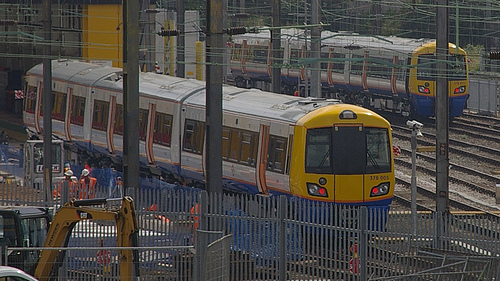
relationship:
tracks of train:
[300, 108, 497, 280] [16, 52, 402, 252]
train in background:
[225, 22, 477, 123] [135, 7, 499, 94]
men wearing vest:
[79, 165, 104, 206] [79, 176, 98, 196]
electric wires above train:
[3, 4, 498, 77] [16, 52, 402, 252]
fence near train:
[7, 175, 498, 277] [16, 52, 402, 252]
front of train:
[291, 104, 399, 257] [16, 52, 402, 252]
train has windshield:
[16, 52, 402, 252] [305, 121, 395, 175]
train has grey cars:
[16, 52, 402, 252] [18, 45, 298, 231]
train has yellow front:
[16, 52, 402, 252] [291, 104, 399, 257]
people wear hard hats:
[44, 158, 208, 238] [64, 168, 91, 176]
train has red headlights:
[16, 52, 402, 252] [317, 183, 381, 198]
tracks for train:
[300, 108, 497, 280] [16, 52, 402, 252]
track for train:
[378, 106, 496, 280] [16, 52, 402, 252]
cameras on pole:
[401, 112, 427, 241] [409, 129, 423, 248]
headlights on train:
[307, 182, 394, 201] [16, 52, 402, 252]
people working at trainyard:
[44, 158, 208, 238] [4, 149, 243, 279]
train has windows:
[16, 52, 402, 252] [24, 79, 290, 173]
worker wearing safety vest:
[145, 201, 171, 223] [144, 213, 168, 225]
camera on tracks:
[401, 112, 427, 241] [300, 108, 497, 280]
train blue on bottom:
[16, 52, 402, 252] [242, 190, 393, 229]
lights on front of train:
[307, 182, 394, 201] [16, 52, 402, 252]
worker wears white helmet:
[58, 167, 80, 200] [62, 168, 75, 177]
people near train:
[44, 158, 208, 238] [150, 73, 390, 215]